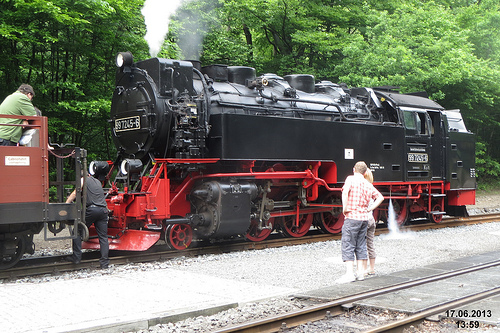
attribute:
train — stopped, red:
[0, 51, 478, 270]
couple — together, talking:
[343, 159, 382, 285]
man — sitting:
[63, 168, 113, 274]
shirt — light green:
[0, 92, 41, 148]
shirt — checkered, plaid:
[341, 174, 380, 223]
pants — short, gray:
[341, 219, 373, 261]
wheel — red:
[167, 221, 198, 253]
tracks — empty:
[220, 257, 500, 332]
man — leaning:
[0, 84, 45, 147]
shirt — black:
[76, 176, 112, 210]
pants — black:
[72, 204, 112, 271]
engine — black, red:
[154, 55, 379, 251]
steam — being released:
[140, 1, 222, 63]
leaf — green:
[293, 33, 304, 45]